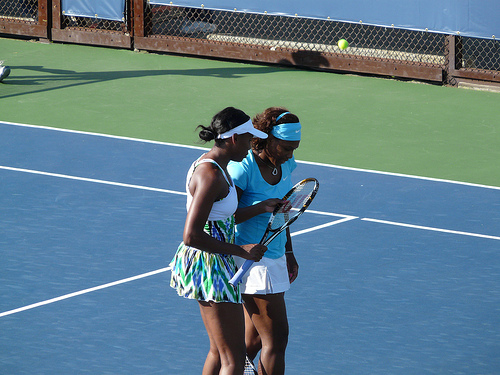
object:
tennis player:
[169, 107, 290, 373]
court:
[1, 39, 499, 374]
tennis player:
[227, 107, 300, 374]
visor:
[217, 117, 268, 139]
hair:
[197, 106, 251, 140]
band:
[270, 123, 302, 142]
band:
[275, 112, 292, 121]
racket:
[227, 176, 319, 285]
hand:
[241, 243, 268, 262]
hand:
[264, 198, 292, 214]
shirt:
[225, 150, 297, 259]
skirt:
[230, 252, 290, 296]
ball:
[337, 39, 348, 50]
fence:
[0, 1, 499, 85]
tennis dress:
[169, 151, 245, 302]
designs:
[169, 215, 241, 304]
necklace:
[254, 152, 282, 176]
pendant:
[272, 168, 278, 176]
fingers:
[266, 197, 288, 206]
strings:
[295, 186, 307, 196]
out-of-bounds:
[0, 37, 499, 185]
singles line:
[0, 217, 357, 319]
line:
[0, 120, 499, 191]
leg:
[198, 301, 221, 374]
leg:
[203, 301, 245, 374]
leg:
[242, 304, 263, 361]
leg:
[242, 292, 290, 374]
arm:
[182, 175, 242, 255]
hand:
[286, 257, 299, 284]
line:
[1, 164, 499, 240]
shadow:
[2, 36, 331, 99]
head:
[211, 107, 253, 163]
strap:
[194, 159, 232, 188]